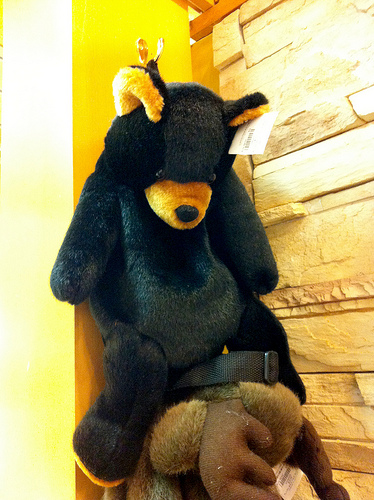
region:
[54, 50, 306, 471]
black and tan stuffed teddy bear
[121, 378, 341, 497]
stuffed moose toy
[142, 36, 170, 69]
hook bear toy is hanging from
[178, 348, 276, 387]
black strap on moose toy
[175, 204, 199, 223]
black nose of bear toy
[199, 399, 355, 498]
brown antlers on moose toy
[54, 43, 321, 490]
this is a stuffed animal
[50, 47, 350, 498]
stuffed animal is black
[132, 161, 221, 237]
brown fur on bear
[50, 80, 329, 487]
the bear is black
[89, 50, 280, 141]
brown ears on bear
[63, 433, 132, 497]
brown paw on bear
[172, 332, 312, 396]
black strap under bear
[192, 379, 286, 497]
a stuffed animal antler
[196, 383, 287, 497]
the antler is brown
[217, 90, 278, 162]
tag on the bears ear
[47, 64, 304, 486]
a black and brown teddy bear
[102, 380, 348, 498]
stuffed brown toy moose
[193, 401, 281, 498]
a toy moose's antler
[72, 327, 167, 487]
a teddy bear's right leg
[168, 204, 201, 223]
a teddy bear's black nose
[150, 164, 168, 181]
a teddy bear's right eye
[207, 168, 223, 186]
a teddy bear's left eye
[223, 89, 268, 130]
a teddy bear's left ear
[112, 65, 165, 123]
a teddy bear's right ear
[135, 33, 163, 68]
brass wall hook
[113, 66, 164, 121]
bear has an ear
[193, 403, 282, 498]
antler is brown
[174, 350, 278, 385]
belt has a buckle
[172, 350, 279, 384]
belt is black and metal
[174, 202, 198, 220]
bear has a black nose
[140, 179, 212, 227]
bear has a brown snout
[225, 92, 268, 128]
bears ear is brown and black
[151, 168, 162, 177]
bear has a black eye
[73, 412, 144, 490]
bear has black and brown feet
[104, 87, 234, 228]
bear head is black and brown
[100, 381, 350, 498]
Large brown stuffed animal.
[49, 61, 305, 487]
Large stuffed black bear on hook.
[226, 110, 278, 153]
White tag on a bear.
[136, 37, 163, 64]
Silver hook with a bear on it.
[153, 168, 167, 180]
Glass eye on a bear.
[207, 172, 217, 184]
Glass eye on a bear.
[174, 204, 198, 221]
Black nose on a bear.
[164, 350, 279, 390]
Black strap under a bear.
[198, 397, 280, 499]
Stuffed large brown antler.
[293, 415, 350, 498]
Stuffed large brown antler.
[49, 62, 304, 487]
A black teddy bear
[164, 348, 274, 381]
A black strap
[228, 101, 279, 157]
A tag on a teddy bear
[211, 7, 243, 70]
brick is yellow and brown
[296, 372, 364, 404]
brick is yellow and brown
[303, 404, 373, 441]
brick is yellow and brown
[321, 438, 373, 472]
brick is yellow and brown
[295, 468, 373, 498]
brick is yellow and brown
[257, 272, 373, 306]
brick is yellow and brownbrick is yellow and brown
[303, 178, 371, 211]
brick is yellow and brown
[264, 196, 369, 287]
brick is yellow and brown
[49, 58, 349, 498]
black teddy bear on brown moose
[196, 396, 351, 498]
two cloth brown moose antlers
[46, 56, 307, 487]
black teddy bear with brown face